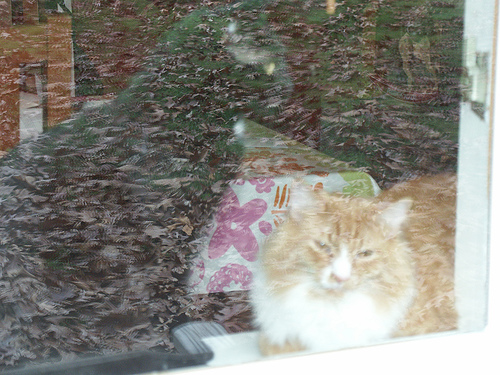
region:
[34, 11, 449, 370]
two cats in window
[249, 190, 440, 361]
white and tan tabby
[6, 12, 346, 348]
black cat sitting in window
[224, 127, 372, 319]
white cardboard box with designs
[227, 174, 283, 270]
pink flower designs on box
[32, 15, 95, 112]
wooden bed post by cat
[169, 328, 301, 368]
white table under cats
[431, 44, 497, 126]
metal latch on wall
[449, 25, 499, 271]
white frame on right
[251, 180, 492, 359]
orange and white cat in window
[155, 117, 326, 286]
box wrapped in white paper with floral details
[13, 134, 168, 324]
reflection of leafs on lawn in window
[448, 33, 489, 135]
chrome hardware for window on white frame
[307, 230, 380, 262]
hazel cat eyes surrounded by orange fur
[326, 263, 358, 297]
white and pink nose on cat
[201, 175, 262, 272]
pink flower on white background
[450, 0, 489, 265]
white painted wood window frame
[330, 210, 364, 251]
dark orange stripes in light orange fur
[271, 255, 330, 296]
long white whiskers on cat's face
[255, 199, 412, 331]
cat looking to the left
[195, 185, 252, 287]
pink designs near cat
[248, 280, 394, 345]
white fur on cat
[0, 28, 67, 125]
wooden chair in background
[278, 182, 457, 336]
cat fur is brown and white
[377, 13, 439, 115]
blurred reflection in background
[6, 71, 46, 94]
picture on the wall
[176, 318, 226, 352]
remote by the cat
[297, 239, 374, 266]
cat has green eyes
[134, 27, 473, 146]
green coloring in background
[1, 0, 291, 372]
The black cat in the window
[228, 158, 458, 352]
The orange cat in the window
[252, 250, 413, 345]
The white section of the orange cat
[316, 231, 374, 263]
The eyes of the orange cat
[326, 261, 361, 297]
The nose of the orange cat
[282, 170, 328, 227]
The orange cat's right ear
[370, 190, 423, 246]
The orange cat's left ear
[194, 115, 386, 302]
The flower print table cloth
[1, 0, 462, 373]
The grass and leaves relected in the window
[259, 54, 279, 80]
The right eye of the black cat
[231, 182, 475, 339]
brown and white cat in window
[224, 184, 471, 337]
big brown cat in window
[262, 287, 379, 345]
white fur on cat in window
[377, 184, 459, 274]
brown fur on cat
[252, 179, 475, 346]
big fluffy brown and white cat in window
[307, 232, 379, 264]
cat's eyes are open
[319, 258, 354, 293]
cat's mouth and nose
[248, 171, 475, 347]
brown and white fluffy cat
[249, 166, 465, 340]
big fluffy cat on bed